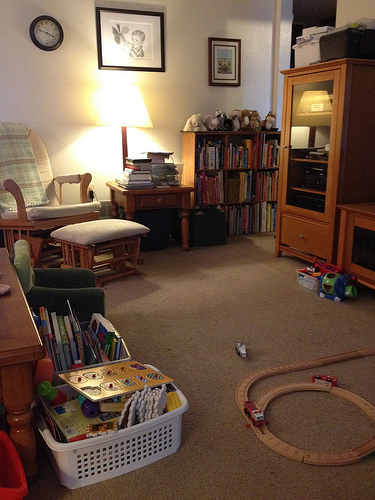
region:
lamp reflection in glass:
[291, 86, 332, 151]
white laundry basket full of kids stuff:
[30, 362, 190, 490]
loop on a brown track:
[247, 380, 373, 465]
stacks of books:
[118, 149, 178, 189]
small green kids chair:
[9, 239, 105, 323]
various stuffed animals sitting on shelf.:
[181, 107, 276, 129]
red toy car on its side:
[313, 368, 337, 387]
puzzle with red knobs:
[55, 356, 173, 402]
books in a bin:
[29, 301, 129, 370]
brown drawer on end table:
[140, 191, 180, 209]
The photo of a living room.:
[0, 0, 372, 497]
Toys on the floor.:
[232, 256, 368, 463]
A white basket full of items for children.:
[34, 306, 184, 486]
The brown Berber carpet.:
[188, 315, 226, 427]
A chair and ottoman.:
[0, 120, 147, 276]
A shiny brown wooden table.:
[0, 289, 40, 465]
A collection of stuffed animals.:
[175, 105, 276, 124]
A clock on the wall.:
[27, 13, 67, 50]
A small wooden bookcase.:
[189, 129, 279, 238]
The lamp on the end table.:
[91, 80, 194, 250]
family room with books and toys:
[40, 50, 362, 408]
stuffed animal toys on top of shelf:
[181, 106, 277, 132]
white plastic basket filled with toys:
[36, 348, 198, 488]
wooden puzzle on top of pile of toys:
[56, 355, 171, 400]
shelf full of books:
[186, 129, 273, 246]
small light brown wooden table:
[110, 178, 189, 248]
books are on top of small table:
[104, 150, 189, 195]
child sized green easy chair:
[7, 235, 121, 321]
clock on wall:
[2, 2, 83, 67]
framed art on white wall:
[89, 1, 256, 97]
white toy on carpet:
[229, 337, 259, 361]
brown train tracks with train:
[214, 359, 374, 494]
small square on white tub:
[67, 448, 180, 476]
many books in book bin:
[33, 306, 158, 356]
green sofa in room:
[6, 238, 127, 328]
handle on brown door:
[285, 225, 316, 245]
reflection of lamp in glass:
[289, 70, 355, 126]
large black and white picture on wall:
[91, 4, 184, 79]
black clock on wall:
[11, 6, 81, 62]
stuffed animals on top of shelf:
[189, 101, 295, 140]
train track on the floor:
[238, 344, 374, 459]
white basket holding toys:
[28, 384, 189, 490]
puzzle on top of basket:
[58, 358, 180, 400]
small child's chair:
[12, 236, 111, 323]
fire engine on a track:
[241, 397, 266, 428]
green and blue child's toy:
[322, 267, 356, 307]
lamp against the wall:
[88, 75, 158, 175]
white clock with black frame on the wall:
[30, 14, 64, 50]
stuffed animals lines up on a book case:
[181, 104, 280, 130]